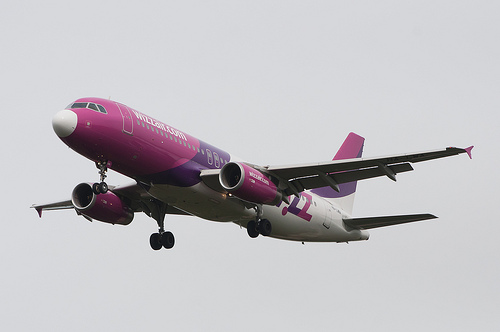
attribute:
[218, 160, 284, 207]
turbine engine — purple, one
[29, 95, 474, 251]
plane — purple, white, violet, flying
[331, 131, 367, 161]
tail — purple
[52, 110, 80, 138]
nose — white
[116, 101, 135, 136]
plane door — closed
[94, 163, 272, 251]
landing gear — out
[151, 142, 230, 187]
stripe — purple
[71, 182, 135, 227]
engine — purple, one